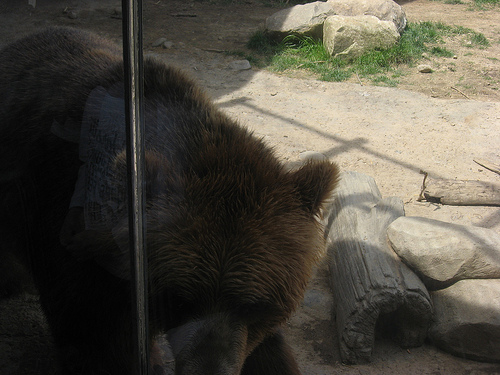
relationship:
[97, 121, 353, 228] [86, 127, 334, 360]
ears on head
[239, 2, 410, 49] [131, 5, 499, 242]
stones on ground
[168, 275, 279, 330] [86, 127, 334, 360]
eyes on face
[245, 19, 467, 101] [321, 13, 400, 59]
grass near rocks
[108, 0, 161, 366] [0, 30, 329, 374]
pole near bear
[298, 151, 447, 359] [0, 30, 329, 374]
log near bear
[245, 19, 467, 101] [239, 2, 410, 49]
grass near rocks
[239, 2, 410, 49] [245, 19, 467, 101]
rocks near grass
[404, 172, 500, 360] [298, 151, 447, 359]
rocks next to log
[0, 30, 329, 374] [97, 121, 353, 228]
bear has ear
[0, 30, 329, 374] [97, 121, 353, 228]
bear has ears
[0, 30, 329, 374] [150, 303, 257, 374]
bear has snout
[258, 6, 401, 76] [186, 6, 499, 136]
rocks in background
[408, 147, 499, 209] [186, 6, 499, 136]
bark in background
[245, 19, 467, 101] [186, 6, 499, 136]
grass in background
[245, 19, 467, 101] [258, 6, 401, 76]
grass near rocks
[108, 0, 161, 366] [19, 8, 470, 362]
pane between windows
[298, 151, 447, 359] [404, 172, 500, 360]
tree trunk near rocks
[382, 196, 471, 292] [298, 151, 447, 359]
rock on trunk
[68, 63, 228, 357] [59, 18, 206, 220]
reflection of boy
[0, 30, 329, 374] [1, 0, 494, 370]
bear in zoo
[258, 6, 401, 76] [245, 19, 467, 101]
rocks near grass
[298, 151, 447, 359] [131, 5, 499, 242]
log on ground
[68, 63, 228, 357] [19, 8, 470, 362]
reflection in glass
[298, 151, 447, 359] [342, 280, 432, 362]
log has hole